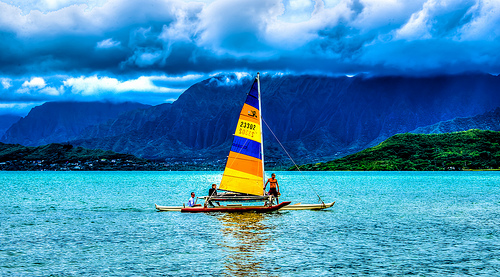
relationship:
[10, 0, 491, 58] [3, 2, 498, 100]
clouds are in sky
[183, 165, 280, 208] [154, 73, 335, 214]
people on boat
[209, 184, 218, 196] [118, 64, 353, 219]
people in sailboat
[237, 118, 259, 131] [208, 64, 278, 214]
number on sail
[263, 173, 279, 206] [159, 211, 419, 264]
man in water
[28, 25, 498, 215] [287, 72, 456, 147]
mountains in background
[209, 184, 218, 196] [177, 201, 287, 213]
people on boat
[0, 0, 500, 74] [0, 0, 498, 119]
clouds in sky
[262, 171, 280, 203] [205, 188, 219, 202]
man wearing shirt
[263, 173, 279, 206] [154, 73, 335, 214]
man standing boat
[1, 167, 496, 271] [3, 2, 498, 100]
water reflecting sky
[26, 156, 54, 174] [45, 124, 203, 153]
buildings in distance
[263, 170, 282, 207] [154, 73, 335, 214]
man on boat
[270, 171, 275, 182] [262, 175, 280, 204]
head on man